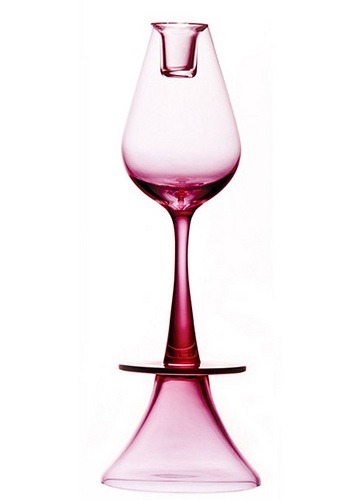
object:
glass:
[101, 21, 264, 492]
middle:
[163, 216, 203, 367]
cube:
[150, 21, 207, 79]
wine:
[136, 171, 229, 215]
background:
[1, 171, 141, 313]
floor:
[50, 457, 125, 497]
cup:
[119, 22, 245, 375]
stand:
[118, 340, 249, 401]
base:
[101, 374, 262, 490]